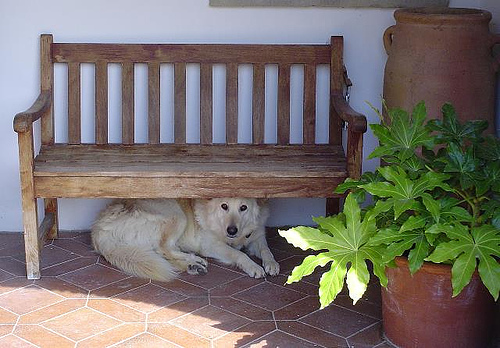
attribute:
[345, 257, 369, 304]
leaf —  artificial 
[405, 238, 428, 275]
leaf —  artificial 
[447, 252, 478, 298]
leaf —  artificial 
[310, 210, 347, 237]
leaf —  artificial 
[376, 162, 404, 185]
leaf —  artificial 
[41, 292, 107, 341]
floor —  tile ,  white and brown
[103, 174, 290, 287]
dog — laying down, tan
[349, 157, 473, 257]
leaf — bright green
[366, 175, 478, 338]
plant — green, potted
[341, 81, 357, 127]
chain —  metal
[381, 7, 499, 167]
pot —  clay,   tall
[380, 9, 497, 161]
clay pot —   clay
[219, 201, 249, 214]
eyes — open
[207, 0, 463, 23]
window —  wooden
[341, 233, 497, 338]
ceramic —  pot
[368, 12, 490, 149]
pot —  ceramic ,  big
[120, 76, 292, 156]
bench —  wooden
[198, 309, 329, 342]
tiles —  floor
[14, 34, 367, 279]
bench —  wooden ,  empty